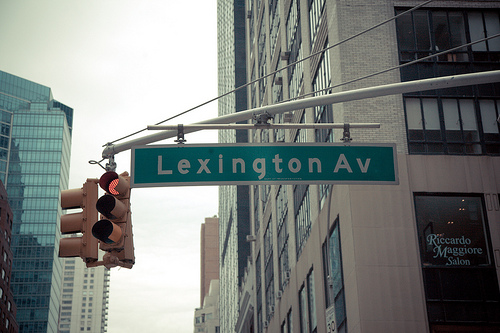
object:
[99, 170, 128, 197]
signal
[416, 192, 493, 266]
window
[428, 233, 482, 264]
riccardo maggiore sa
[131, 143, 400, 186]
sign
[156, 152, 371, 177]
lexington avenue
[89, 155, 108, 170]
wire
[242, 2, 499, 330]
building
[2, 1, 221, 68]
sky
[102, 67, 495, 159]
pole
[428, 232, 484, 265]
decal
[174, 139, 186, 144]
bracket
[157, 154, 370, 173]
street name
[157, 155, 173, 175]
writing